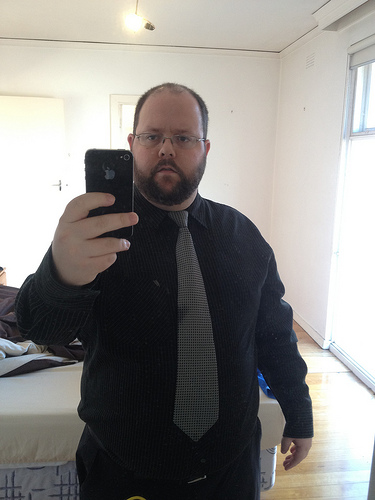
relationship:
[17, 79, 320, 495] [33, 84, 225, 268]
man taking selfie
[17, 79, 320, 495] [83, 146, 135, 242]
man holding iphone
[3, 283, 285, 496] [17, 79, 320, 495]
bed behind man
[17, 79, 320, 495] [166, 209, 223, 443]
man wearing tie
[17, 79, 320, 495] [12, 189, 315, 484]
man wearing shirt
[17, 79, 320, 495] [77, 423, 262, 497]
man wearing pants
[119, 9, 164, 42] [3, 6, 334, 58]
light on ceiling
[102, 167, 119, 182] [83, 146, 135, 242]
apple logo on phone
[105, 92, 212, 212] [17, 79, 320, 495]
door behind man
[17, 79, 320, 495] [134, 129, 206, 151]
man wears glasses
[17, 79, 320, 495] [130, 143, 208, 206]
man has beard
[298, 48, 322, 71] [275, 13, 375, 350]
vent in wall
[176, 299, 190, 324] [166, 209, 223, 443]
stain on tie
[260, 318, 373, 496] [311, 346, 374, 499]
floor reflecting light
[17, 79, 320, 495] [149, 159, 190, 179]
man has moustache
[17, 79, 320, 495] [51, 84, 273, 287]
man taking selfie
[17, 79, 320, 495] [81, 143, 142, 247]
man uses phone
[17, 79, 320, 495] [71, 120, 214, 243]
man taking selfie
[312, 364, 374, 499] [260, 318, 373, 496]
shining light on floor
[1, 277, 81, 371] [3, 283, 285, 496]
comforter on bed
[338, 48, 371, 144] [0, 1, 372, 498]
open window in room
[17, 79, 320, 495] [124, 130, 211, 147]
man wearing rimless glasses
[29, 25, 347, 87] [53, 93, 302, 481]
wall behind man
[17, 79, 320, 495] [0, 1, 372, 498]
man in room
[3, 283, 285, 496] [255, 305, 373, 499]
bed on floor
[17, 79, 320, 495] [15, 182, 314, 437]
man wearing shirt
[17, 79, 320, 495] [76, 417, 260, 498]
man wearing pants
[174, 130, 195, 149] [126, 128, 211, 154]
lense on glasses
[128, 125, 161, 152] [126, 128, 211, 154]
lense on glasses